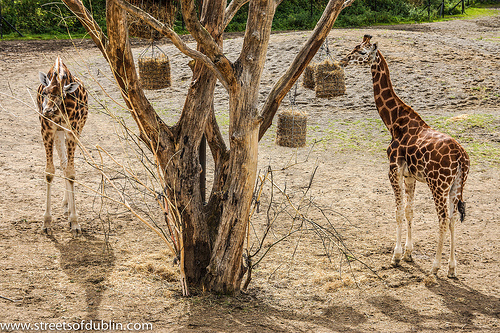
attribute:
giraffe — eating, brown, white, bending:
[14, 42, 87, 200]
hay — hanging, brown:
[139, 62, 184, 99]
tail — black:
[454, 158, 476, 226]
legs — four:
[44, 170, 79, 209]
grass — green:
[42, 32, 63, 42]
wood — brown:
[109, 1, 122, 18]